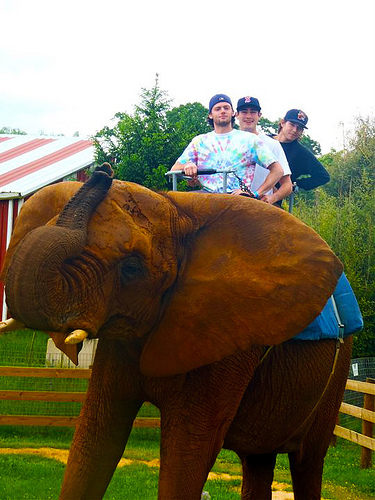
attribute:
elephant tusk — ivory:
[65, 336, 81, 344]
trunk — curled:
[7, 162, 116, 338]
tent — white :
[2, 128, 99, 212]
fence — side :
[332, 374, 374, 454]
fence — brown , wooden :
[0, 365, 374, 467]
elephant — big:
[0, 160, 352, 499]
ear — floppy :
[138, 190, 343, 377]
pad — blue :
[296, 270, 364, 336]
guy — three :
[166, 91, 282, 197]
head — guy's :
[279, 109, 309, 141]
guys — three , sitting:
[166, 90, 333, 210]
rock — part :
[198, 477, 206, 498]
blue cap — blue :
[208, 91, 234, 114]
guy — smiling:
[236, 95, 264, 128]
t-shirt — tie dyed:
[173, 127, 280, 193]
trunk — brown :
[19, 183, 149, 298]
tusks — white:
[0, 317, 90, 346]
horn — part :
[58, 330, 87, 344]